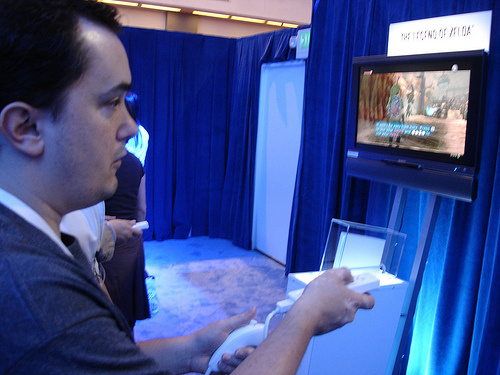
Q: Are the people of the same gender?
A: No, they are both male and female.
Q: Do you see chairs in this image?
A: No, there are no chairs.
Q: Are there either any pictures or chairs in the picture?
A: No, there are no chairs or pictures.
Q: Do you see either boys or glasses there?
A: No, there are no glasses or boys.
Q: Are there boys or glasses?
A: No, there are no glasses or boys.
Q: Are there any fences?
A: No, there are no fences.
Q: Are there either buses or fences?
A: No, there are no fences or buses.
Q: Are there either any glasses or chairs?
A: No, there are no chairs or glasses.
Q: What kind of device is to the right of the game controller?
A: The device is a Wii.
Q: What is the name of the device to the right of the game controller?
A: The device is a Wii.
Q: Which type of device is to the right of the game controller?
A: The device is a Wii.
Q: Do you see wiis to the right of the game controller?
A: Yes, there is a Wii to the right of the game controller.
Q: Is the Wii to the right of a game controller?
A: Yes, the Wii is to the right of a game controller.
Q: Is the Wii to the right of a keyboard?
A: No, the Wii is to the right of a game controller.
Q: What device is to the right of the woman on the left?
A: The device is a Wii.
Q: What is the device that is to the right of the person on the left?
A: The device is a Wii.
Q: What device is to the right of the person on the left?
A: The device is a Wii.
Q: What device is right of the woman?
A: The device is a Wii.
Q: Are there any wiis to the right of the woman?
A: Yes, there is a Wii to the right of the woman.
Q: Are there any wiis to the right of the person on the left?
A: Yes, there is a Wii to the right of the woman.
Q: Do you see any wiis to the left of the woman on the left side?
A: No, the Wii is to the right of the woman.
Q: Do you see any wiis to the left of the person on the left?
A: No, the Wii is to the right of the woman.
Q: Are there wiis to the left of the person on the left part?
A: No, the Wii is to the right of the woman.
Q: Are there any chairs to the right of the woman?
A: No, there is a Wii to the right of the woman.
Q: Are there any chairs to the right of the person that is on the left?
A: No, there is a Wii to the right of the woman.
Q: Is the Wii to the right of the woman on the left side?
A: Yes, the Wii is to the right of the woman.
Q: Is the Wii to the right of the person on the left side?
A: Yes, the Wii is to the right of the woman.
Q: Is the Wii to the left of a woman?
A: No, the Wii is to the right of a woman.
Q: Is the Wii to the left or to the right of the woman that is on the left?
A: The Wii is to the right of the woman.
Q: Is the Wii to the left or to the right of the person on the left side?
A: The Wii is to the right of the woman.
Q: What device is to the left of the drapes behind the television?
A: The device is a Wii.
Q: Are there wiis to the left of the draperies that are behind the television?
A: Yes, there is a Wii to the left of the drapes.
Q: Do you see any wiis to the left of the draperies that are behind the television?
A: Yes, there is a Wii to the left of the drapes.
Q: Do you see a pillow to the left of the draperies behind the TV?
A: No, there is a Wii to the left of the draperies.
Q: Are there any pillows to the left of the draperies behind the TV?
A: No, there is a Wii to the left of the draperies.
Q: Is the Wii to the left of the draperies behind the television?
A: Yes, the Wii is to the left of the draperies.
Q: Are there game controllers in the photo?
A: Yes, there is a game controller.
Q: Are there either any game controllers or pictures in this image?
A: Yes, there is a game controller.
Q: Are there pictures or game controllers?
A: Yes, there is a game controller.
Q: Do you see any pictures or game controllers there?
A: Yes, there is a game controller.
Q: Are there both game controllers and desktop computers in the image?
A: No, there is a game controller but no desktop computers.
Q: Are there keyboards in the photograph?
A: No, there are no keyboards.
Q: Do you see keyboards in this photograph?
A: No, there are no keyboards.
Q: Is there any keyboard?
A: No, there are no keyboards.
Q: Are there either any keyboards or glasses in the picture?
A: No, there are no keyboards or glasses.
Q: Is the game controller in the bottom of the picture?
A: Yes, the game controller is in the bottom of the image.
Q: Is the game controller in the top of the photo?
A: No, the game controller is in the bottom of the image.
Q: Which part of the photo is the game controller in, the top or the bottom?
A: The game controller is in the bottom of the image.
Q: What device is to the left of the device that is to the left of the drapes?
A: The device is a game controller.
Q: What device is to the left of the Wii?
A: The device is a game controller.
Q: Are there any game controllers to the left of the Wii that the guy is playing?
A: Yes, there is a game controller to the left of the Wii.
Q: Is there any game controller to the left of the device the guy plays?
A: Yes, there is a game controller to the left of the Wii.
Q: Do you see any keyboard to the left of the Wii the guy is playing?
A: No, there is a game controller to the left of the Wii.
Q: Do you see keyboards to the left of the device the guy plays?
A: No, there is a game controller to the left of the Wii.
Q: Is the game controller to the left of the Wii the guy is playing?
A: Yes, the game controller is to the left of the Wii.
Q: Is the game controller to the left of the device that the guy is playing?
A: Yes, the game controller is to the left of the Wii.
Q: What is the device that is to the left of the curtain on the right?
A: The device is a game controller.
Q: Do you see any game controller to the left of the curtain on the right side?
A: Yes, there is a game controller to the left of the curtain.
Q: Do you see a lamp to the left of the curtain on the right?
A: No, there is a game controller to the left of the curtain.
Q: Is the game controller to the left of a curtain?
A: Yes, the game controller is to the left of a curtain.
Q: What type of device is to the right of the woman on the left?
A: The device is a game controller.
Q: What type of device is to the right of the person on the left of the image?
A: The device is a game controller.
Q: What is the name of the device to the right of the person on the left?
A: The device is a game controller.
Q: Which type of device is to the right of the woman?
A: The device is a game controller.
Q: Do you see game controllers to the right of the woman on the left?
A: Yes, there is a game controller to the right of the woman.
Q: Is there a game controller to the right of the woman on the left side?
A: Yes, there is a game controller to the right of the woman.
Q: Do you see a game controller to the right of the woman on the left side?
A: Yes, there is a game controller to the right of the woman.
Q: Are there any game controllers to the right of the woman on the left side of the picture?
A: Yes, there is a game controller to the right of the woman.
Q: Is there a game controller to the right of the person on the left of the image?
A: Yes, there is a game controller to the right of the woman.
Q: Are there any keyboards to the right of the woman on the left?
A: No, there is a game controller to the right of the woman.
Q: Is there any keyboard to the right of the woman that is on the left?
A: No, there is a game controller to the right of the woman.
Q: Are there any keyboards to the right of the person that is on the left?
A: No, there is a game controller to the right of the woman.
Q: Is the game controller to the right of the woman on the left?
A: Yes, the game controller is to the right of the woman.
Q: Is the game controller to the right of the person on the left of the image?
A: Yes, the game controller is to the right of the woman.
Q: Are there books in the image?
A: No, there are no books.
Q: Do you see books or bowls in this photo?
A: No, there are no books or bowls.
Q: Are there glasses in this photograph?
A: No, there are no glasses.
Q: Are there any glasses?
A: No, there are no glasses.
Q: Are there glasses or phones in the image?
A: No, there are no glasses or phones.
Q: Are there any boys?
A: No, there are no boys.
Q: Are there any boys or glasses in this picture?
A: No, there are no boys or glasses.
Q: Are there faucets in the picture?
A: No, there are no faucets.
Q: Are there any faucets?
A: No, there are no faucets.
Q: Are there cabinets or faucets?
A: No, there are no faucets or cabinets.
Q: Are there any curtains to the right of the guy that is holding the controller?
A: Yes, there is a curtain to the right of the guy.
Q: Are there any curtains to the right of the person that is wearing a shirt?
A: Yes, there is a curtain to the right of the guy.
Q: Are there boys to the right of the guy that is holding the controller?
A: No, there is a curtain to the right of the guy.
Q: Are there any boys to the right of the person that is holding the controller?
A: No, there is a curtain to the right of the guy.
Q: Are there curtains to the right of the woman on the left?
A: Yes, there is a curtain to the right of the woman.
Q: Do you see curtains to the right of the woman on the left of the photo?
A: Yes, there is a curtain to the right of the woman.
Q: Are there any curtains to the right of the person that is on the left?
A: Yes, there is a curtain to the right of the woman.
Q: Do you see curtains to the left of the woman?
A: No, the curtain is to the right of the woman.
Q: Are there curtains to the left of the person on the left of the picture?
A: No, the curtain is to the right of the woman.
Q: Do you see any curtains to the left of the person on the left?
A: No, the curtain is to the right of the woman.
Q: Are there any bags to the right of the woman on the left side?
A: No, there is a curtain to the right of the woman.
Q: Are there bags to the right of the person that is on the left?
A: No, there is a curtain to the right of the woman.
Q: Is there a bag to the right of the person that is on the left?
A: No, there is a curtain to the right of the woman.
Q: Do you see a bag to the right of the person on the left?
A: No, there is a curtain to the right of the woman.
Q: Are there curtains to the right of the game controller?
A: Yes, there is a curtain to the right of the game controller.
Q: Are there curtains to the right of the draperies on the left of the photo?
A: Yes, there is a curtain to the right of the draperies.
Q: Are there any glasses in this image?
A: No, there are no glasses.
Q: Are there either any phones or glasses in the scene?
A: No, there are no glasses or phones.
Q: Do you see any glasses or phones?
A: No, there are no glasses or phones.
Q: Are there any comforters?
A: No, there are no comforters.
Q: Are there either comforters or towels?
A: No, there are no comforters or towels.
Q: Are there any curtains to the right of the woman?
A: Yes, there is a curtain to the right of the woman.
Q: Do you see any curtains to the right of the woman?
A: Yes, there is a curtain to the right of the woman.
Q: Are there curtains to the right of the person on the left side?
A: Yes, there is a curtain to the right of the woman.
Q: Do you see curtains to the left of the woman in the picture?
A: No, the curtain is to the right of the woman.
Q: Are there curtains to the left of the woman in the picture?
A: No, the curtain is to the right of the woman.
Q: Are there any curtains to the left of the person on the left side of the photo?
A: No, the curtain is to the right of the woman.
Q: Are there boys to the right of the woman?
A: No, there is a curtain to the right of the woman.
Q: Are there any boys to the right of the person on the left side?
A: No, there is a curtain to the right of the woman.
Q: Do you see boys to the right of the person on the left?
A: No, there is a curtain to the right of the woman.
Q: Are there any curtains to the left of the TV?
A: Yes, there is a curtain to the left of the TV.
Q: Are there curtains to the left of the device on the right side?
A: Yes, there is a curtain to the left of the TV.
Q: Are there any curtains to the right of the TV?
A: No, the curtain is to the left of the TV.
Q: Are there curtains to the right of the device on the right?
A: No, the curtain is to the left of the TV.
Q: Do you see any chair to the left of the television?
A: No, there is a curtain to the left of the television.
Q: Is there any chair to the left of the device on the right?
A: No, there is a curtain to the left of the television.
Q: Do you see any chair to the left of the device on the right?
A: No, there is a curtain to the left of the television.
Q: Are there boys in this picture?
A: No, there are no boys.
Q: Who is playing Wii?
A: The guy is playing wii.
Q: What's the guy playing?
A: The guy is playing wii.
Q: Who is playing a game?
A: The guy is playing a game.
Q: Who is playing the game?
A: The guy is playing a game.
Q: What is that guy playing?
A: The guy is playing a game.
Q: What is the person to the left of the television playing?
A: The guy is playing a game.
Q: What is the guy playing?
A: The guy is playing a game.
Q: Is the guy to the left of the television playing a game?
A: Yes, the guy is playing a game.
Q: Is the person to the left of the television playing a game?
A: Yes, the guy is playing a game.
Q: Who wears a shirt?
A: The guy wears a shirt.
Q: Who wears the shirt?
A: The guy wears a shirt.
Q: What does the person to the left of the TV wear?
A: The guy wears a shirt.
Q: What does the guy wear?
A: The guy wears a shirt.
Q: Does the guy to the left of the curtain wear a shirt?
A: Yes, the guy wears a shirt.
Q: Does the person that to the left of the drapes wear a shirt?
A: Yes, the guy wears a shirt.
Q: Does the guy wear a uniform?
A: No, the guy wears a shirt.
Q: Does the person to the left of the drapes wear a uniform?
A: No, the guy wears a shirt.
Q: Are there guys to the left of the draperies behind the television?
A: Yes, there is a guy to the left of the draperies.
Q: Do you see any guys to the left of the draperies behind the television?
A: Yes, there is a guy to the left of the draperies.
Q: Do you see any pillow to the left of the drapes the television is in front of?
A: No, there is a guy to the left of the drapes.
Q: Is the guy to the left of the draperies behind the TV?
A: Yes, the guy is to the left of the drapes.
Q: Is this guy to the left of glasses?
A: No, the guy is to the left of the drapes.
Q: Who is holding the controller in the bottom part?
A: The guy is holding the controller.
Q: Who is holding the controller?
A: The guy is holding the controller.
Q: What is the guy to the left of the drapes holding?
A: The guy is holding the controller.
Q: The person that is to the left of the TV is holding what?
A: The guy is holding the controller.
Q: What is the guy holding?
A: The guy is holding the controller.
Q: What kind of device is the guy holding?
A: The guy is holding the controller.